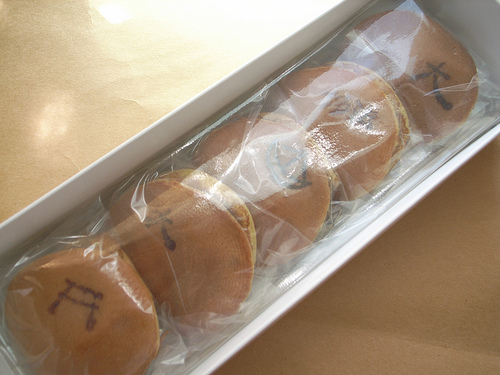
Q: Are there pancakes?
A: Yes, there is a pancake.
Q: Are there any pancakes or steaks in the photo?
A: Yes, there is a pancake.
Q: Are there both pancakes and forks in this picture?
A: No, there is a pancake but no forks.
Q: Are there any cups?
A: No, there are no cups.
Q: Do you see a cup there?
A: No, there are no cups.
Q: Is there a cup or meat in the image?
A: No, there are no cups or meats.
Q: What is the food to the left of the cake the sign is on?
A: The food is a pancake.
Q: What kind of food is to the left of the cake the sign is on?
A: The food is a pancake.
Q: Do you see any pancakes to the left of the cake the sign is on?
A: Yes, there is a pancake to the left of the cake.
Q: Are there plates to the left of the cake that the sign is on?
A: No, there is a pancake to the left of the cake.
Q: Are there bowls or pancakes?
A: Yes, there is a pancake.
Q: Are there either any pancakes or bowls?
A: Yes, there is a pancake.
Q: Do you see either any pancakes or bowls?
A: Yes, there is a pancake.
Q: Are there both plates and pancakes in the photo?
A: No, there is a pancake but no plates.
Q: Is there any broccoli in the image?
A: No, there is no broccoli.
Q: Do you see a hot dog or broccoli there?
A: No, there are no broccoli or hot dogs.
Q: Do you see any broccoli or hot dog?
A: No, there are no broccoli or hot dogs.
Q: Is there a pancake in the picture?
A: Yes, there is a pancake.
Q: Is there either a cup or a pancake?
A: Yes, there is a pancake.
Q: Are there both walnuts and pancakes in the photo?
A: No, there is a pancake but no walnuts.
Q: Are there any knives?
A: No, there are no knives.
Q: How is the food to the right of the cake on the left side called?
A: The food is a pancake.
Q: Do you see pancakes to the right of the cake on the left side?
A: Yes, there is a pancake to the right of the cake.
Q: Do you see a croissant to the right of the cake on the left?
A: No, there is a pancake to the right of the cake.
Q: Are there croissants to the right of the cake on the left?
A: No, there is a pancake to the right of the cake.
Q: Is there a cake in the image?
A: Yes, there is a cake.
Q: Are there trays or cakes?
A: Yes, there is a cake.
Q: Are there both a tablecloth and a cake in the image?
A: No, there is a cake but no tablecloths.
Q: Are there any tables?
A: Yes, there is a table.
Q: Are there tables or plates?
A: Yes, there is a table.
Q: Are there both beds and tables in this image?
A: No, there is a table but no beds.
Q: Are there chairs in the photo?
A: No, there are no chairs.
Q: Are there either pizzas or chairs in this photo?
A: No, there are no chairs or pizzas.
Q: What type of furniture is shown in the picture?
A: The furniture is a table.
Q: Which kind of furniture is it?
A: The piece of furniture is a table.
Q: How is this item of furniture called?
A: That is a table.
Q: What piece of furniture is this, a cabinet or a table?
A: That is a table.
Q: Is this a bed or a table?
A: This is a table.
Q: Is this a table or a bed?
A: This is a table.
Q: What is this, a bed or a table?
A: This is a table.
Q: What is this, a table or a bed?
A: This is a table.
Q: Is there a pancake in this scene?
A: Yes, there is a pancake.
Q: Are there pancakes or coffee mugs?
A: Yes, there is a pancake.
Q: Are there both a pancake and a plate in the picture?
A: No, there is a pancake but no plates.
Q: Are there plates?
A: No, there are no plates.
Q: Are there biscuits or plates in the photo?
A: No, there are no plates or biscuits.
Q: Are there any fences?
A: No, there are no fences.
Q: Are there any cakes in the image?
A: Yes, there is a cake.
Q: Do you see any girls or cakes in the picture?
A: Yes, there is a cake.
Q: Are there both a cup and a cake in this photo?
A: No, there is a cake but no cups.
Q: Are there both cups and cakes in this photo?
A: No, there is a cake but no cups.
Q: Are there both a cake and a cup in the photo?
A: No, there is a cake but no cups.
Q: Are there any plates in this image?
A: No, there are no plates.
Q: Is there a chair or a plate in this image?
A: No, there are no plates or chairs.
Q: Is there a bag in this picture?
A: Yes, there is a bag.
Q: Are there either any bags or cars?
A: Yes, there is a bag.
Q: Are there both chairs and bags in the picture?
A: No, there is a bag but no chairs.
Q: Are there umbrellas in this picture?
A: No, there are no umbrellas.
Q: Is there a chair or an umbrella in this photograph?
A: No, there are no umbrellas or chairs.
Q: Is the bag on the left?
A: Yes, the bag is on the left of the image.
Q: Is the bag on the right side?
A: No, the bag is on the left of the image.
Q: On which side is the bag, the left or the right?
A: The bag is on the left of the image.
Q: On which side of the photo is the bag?
A: The bag is on the left of the image.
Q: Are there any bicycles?
A: No, there are no bicycles.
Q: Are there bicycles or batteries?
A: No, there are no bicycles or batteries.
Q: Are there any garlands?
A: No, there are no garlands.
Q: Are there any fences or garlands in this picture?
A: No, there are no garlands or fences.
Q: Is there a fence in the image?
A: No, there are no fences.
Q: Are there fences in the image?
A: No, there are no fences.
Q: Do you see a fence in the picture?
A: No, there are no fences.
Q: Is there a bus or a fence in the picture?
A: No, there are no fences or buses.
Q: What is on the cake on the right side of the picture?
A: The sign is on the cake.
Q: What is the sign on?
A: The sign is on the cake.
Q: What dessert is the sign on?
A: The sign is on the cake.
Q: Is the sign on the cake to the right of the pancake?
A: Yes, the sign is on the cake.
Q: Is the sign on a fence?
A: No, the sign is on the cake.